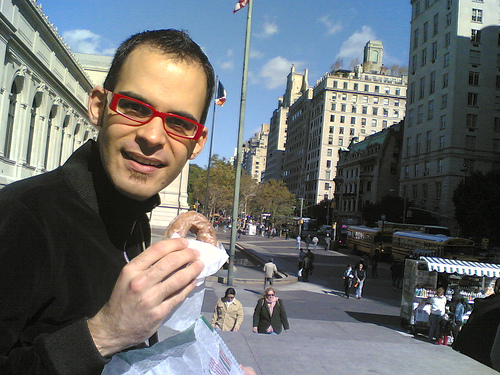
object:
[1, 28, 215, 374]
man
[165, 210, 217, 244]
donut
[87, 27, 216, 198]
head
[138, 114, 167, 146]
nose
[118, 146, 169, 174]
mouth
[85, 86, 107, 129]
ear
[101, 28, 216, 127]
hair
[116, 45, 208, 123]
forehead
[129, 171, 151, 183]
beard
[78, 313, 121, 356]
wrist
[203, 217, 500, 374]
street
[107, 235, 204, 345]
hand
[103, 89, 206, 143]
glasses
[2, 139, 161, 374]
jacket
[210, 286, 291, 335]
two women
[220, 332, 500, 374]
stairs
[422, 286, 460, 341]
two people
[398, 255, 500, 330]
food truck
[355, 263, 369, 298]
people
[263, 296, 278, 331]
shirt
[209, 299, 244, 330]
coat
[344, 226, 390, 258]
bus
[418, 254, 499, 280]
awning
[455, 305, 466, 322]
coat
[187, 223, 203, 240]
hole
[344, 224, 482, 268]
two buses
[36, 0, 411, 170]
sky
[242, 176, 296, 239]
trees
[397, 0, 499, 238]
buildings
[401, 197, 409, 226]
light post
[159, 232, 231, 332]
napkin